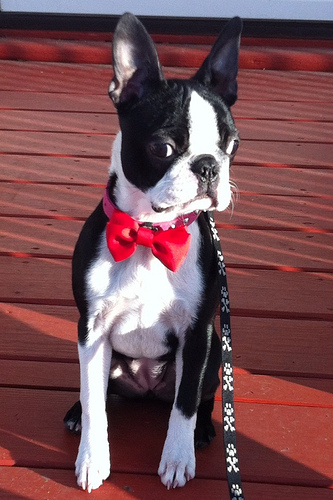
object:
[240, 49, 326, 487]
floor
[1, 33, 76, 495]
floor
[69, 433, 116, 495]
paw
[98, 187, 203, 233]
collar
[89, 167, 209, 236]
neck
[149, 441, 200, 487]
left paw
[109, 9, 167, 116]
ear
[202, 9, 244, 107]
ear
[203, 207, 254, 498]
leash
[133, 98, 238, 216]
face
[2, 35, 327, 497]
deck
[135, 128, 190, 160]
eye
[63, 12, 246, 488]
dog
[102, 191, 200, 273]
bow-tie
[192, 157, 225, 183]
nose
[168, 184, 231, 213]
dog's mouth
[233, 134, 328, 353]
floor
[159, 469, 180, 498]
nails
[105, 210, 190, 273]
tie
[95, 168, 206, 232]
dog's collar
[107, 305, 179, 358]
chest